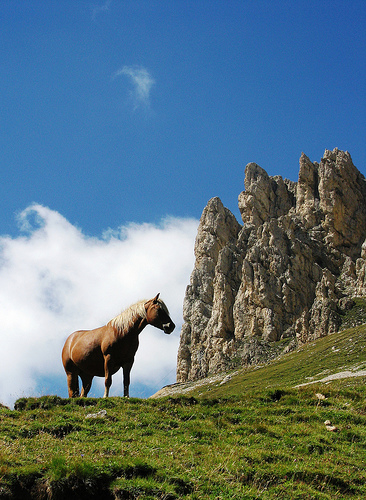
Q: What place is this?
A: It is a field.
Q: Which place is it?
A: It is a field.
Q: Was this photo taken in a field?
A: Yes, it was taken in a field.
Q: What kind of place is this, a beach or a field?
A: It is a field.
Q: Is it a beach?
A: No, it is a field.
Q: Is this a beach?
A: No, it is a field.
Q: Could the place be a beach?
A: No, it is a field.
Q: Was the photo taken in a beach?
A: No, the picture was taken in a field.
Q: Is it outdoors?
A: Yes, it is outdoors.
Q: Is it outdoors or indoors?
A: It is outdoors.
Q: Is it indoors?
A: No, it is outdoors.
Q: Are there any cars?
A: No, there are no cars.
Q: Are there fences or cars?
A: No, there are no cars or fences.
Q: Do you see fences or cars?
A: No, there are no cars or fences.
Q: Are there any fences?
A: No, there are no fences.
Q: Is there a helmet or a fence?
A: No, there are no fences or helmets.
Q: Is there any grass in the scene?
A: Yes, there is grass.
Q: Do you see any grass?
A: Yes, there is grass.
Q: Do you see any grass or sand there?
A: Yes, there is grass.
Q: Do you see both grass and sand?
A: No, there is grass but no sand.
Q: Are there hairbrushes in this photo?
A: No, there are no hairbrushes.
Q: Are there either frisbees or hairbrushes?
A: No, there are no hairbrushes or frisbees.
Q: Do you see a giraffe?
A: No, there are no giraffes.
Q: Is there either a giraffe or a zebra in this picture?
A: No, there are no giraffes or zebras.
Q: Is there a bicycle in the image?
A: No, there are no bicycles.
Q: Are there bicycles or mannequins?
A: No, there are no bicycles or mannequins.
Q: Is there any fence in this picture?
A: No, there are no fences.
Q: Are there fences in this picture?
A: No, there are no fences.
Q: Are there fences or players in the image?
A: No, there are no fences or players.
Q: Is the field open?
A: Yes, the field is open.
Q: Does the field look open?
A: Yes, the field is open.